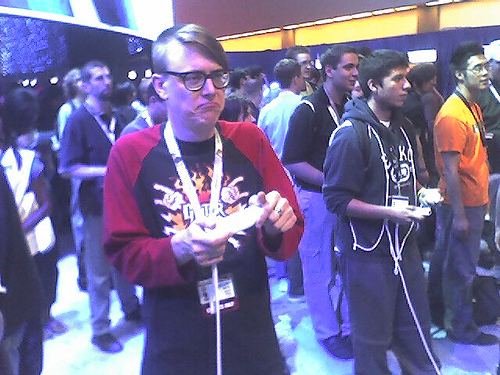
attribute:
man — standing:
[98, 22, 307, 374]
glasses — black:
[163, 67, 231, 92]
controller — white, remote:
[204, 203, 264, 237]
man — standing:
[320, 47, 445, 375]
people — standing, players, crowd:
[0, 22, 499, 375]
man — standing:
[432, 43, 499, 347]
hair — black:
[447, 44, 484, 74]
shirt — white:
[258, 90, 305, 158]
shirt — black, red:
[99, 116, 311, 375]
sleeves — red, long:
[77, 119, 305, 287]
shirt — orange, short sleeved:
[431, 90, 491, 208]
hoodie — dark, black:
[320, 98, 421, 259]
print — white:
[380, 141, 414, 192]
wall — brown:
[172, 2, 498, 101]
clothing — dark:
[320, 100, 440, 374]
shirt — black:
[56, 107, 131, 214]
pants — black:
[335, 246, 442, 375]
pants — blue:
[292, 187, 355, 340]